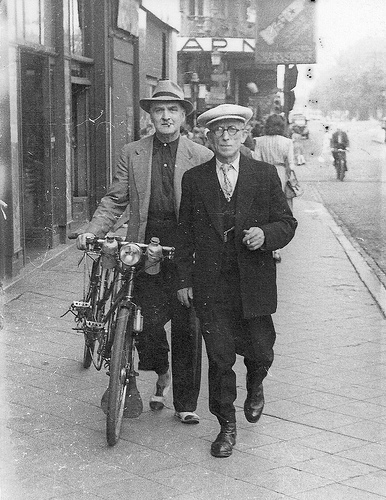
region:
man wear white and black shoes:
[148, 368, 172, 415]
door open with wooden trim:
[15, 46, 53, 264]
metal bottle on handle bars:
[144, 234, 168, 279]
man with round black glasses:
[206, 104, 253, 155]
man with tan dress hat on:
[142, 79, 188, 135]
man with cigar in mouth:
[149, 101, 184, 133]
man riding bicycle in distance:
[331, 126, 350, 180]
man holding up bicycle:
[65, 84, 191, 433]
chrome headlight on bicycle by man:
[118, 241, 142, 268]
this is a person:
[181, 90, 294, 476]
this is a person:
[74, 63, 216, 438]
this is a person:
[315, 112, 354, 200]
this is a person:
[248, 93, 300, 249]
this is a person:
[188, 118, 217, 158]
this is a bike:
[24, 229, 177, 458]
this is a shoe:
[201, 412, 241, 458]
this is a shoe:
[242, 366, 270, 429]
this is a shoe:
[167, 401, 204, 437]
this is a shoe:
[142, 382, 170, 413]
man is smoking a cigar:
[139, 78, 196, 162]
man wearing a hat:
[189, 94, 275, 188]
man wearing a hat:
[116, 70, 192, 172]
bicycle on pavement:
[63, 221, 179, 448]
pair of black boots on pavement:
[208, 379, 271, 462]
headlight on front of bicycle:
[114, 240, 143, 268]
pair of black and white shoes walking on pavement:
[148, 371, 203, 433]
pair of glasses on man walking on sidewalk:
[207, 124, 246, 141]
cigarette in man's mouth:
[164, 119, 175, 130]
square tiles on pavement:
[290, 334, 379, 496]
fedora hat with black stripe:
[134, 74, 196, 116]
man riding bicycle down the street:
[327, 122, 354, 185]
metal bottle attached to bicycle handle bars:
[142, 234, 166, 278]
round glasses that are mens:
[206, 125, 247, 137]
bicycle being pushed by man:
[66, 230, 182, 451]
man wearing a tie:
[215, 162, 236, 197]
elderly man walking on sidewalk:
[169, 107, 300, 460]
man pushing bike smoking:
[77, 76, 215, 437]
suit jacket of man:
[77, 133, 219, 275]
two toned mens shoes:
[145, 370, 169, 414]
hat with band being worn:
[138, 76, 195, 121]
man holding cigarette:
[239, 223, 271, 253]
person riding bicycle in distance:
[327, 120, 354, 181]